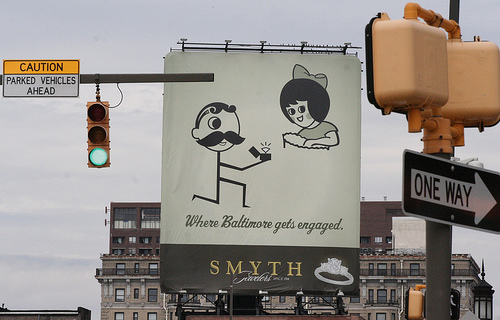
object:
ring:
[257, 142, 274, 154]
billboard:
[153, 39, 367, 300]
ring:
[313, 256, 357, 287]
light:
[87, 146, 111, 167]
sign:
[2, 57, 83, 98]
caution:
[2, 59, 81, 75]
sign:
[399, 147, 498, 235]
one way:
[407, 167, 478, 211]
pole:
[421, 153, 455, 320]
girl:
[278, 61, 342, 156]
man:
[188, 101, 274, 212]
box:
[248, 145, 272, 161]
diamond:
[257, 141, 273, 153]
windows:
[112, 288, 128, 304]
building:
[94, 200, 495, 318]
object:
[363, 0, 497, 158]